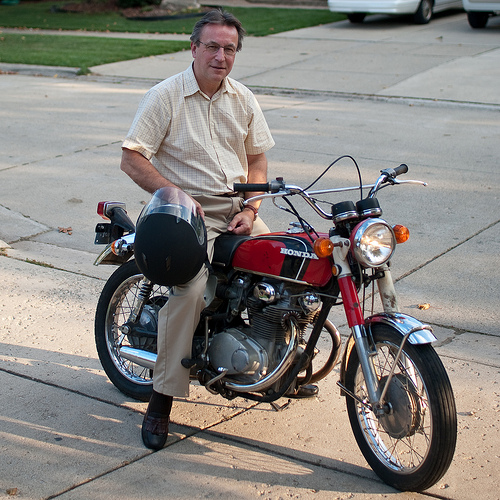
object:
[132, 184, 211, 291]
helmet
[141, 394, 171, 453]
shoe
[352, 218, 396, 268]
headlight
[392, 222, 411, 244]
turn signal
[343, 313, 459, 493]
wheel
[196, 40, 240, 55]
glasses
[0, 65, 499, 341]
street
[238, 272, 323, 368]
engine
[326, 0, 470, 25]
car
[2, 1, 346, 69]
grass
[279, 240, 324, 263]
honda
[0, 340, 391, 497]
shadow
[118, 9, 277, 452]
man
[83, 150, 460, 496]
motorcycle